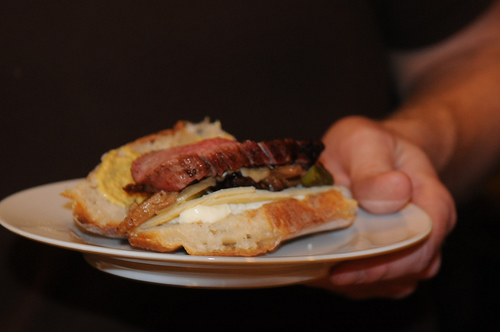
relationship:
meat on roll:
[135, 165, 190, 192] [216, 202, 291, 249]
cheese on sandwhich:
[99, 171, 126, 194] [109, 97, 308, 235]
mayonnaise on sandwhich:
[198, 210, 216, 222] [109, 97, 308, 235]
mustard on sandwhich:
[115, 145, 135, 166] [109, 97, 308, 235]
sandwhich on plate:
[109, 97, 308, 235] [12, 187, 79, 254]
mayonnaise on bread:
[198, 210, 216, 222] [48, 183, 113, 236]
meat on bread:
[135, 165, 190, 192] [48, 183, 113, 236]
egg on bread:
[249, 186, 273, 199] [48, 183, 113, 236]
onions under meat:
[177, 178, 211, 204] [135, 165, 190, 192]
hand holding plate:
[320, 104, 457, 254] [12, 187, 79, 254]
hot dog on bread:
[229, 136, 278, 160] [48, 183, 113, 236]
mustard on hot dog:
[115, 145, 135, 166] [229, 136, 278, 160]